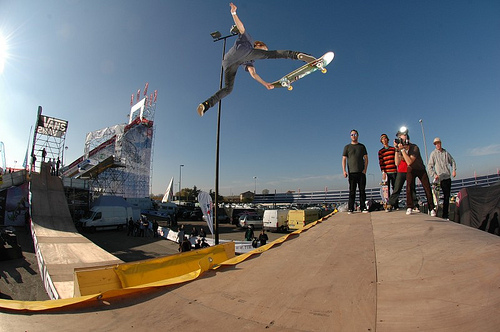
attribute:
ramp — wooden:
[26, 166, 236, 326]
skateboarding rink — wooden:
[23, 164, 228, 290]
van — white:
[257, 200, 289, 237]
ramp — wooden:
[19, 164, 206, 302]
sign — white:
[27, 114, 73, 146]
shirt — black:
[341, 141, 367, 173]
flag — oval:
[193, 184, 216, 236]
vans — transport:
[253, 200, 319, 232]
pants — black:
[342, 167, 368, 213]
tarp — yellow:
[0, 204, 340, 311]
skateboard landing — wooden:
[0, 205, 497, 330]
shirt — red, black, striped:
[375, 147, 399, 176]